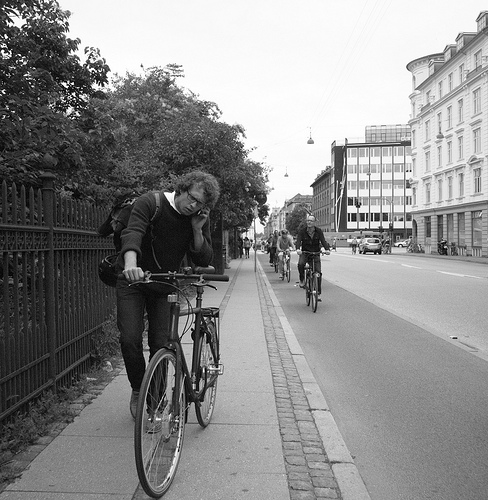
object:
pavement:
[230, 398, 327, 496]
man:
[96, 169, 220, 438]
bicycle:
[117, 264, 231, 497]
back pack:
[98, 184, 159, 254]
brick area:
[288, 453, 311, 492]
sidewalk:
[56, 385, 126, 497]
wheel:
[132, 343, 187, 498]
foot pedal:
[206, 363, 226, 376]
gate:
[2, 179, 118, 427]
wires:
[213, 3, 416, 196]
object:
[307, 127, 315, 145]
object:
[282, 170, 291, 179]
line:
[262, 262, 276, 312]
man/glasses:
[173, 168, 220, 220]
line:
[440, 266, 462, 280]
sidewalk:
[339, 242, 447, 306]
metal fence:
[1, 162, 55, 441]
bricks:
[274, 343, 306, 421]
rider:
[294, 214, 330, 310]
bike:
[289, 247, 330, 311]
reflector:
[166, 292, 180, 304]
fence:
[2, 152, 240, 428]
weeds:
[2, 396, 49, 451]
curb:
[248, 258, 367, 491]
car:
[359, 236, 382, 255]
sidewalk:
[222, 287, 267, 372]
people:
[264, 212, 330, 309]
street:
[461, 402, 486, 497]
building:
[405, 8, 487, 258]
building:
[331, 136, 416, 244]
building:
[309, 165, 333, 234]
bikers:
[277, 229, 297, 285]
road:
[354, 371, 459, 496]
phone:
[198, 203, 210, 217]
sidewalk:
[221, 386, 297, 498]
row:
[255, 221, 330, 307]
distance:
[224, 206, 342, 246]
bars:
[142, 270, 229, 290]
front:
[137, 273, 218, 330]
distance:
[335, 219, 436, 279]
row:
[270, 326, 333, 488]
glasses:
[182, 189, 209, 210]